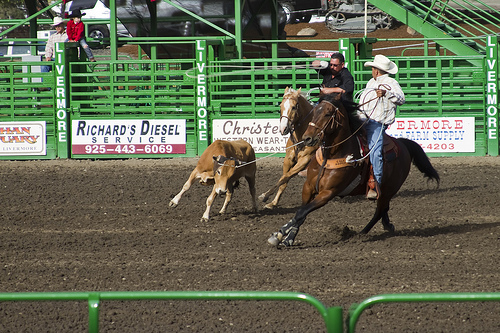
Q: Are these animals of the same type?
A: No, they are horses and bulls.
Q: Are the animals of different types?
A: Yes, they are horses and bulls.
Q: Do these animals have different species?
A: Yes, they are horses and bulls.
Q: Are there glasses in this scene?
A: No, there are no glasses.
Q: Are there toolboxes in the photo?
A: No, there are no toolboxes.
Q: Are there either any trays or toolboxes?
A: No, there are no toolboxes or trays.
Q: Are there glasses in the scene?
A: No, there are no glasses.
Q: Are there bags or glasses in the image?
A: No, there are no glasses or bags.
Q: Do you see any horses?
A: Yes, there is a horse.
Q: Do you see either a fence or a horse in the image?
A: Yes, there is a horse.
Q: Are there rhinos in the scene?
A: No, there are no rhinos.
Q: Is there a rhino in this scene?
A: No, there are no rhinos.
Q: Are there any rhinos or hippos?
A: No, there are no rhinos or hippos.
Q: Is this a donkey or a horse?
A: This is a horse.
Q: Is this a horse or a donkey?
A: This is a horse.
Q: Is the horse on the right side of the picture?
A: Yes, the horse is on the right of the image.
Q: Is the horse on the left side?
A: No, the horse is on the right of the image.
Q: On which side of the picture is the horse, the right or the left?
A: The horse is on the right of the image.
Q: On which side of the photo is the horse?
A: The horse is on the right of the image.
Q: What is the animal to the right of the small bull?
A: The animal is a horse.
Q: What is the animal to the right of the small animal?
A: The animal is a horse.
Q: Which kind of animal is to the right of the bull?
A: The animal is a horse.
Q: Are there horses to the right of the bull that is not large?
A: Yes, there is a horse to the right of the bull.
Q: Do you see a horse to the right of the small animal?
A: Yes, there is a horse to the right of the bull.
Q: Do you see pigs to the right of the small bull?
A: No, there is a horse to the right of the bull.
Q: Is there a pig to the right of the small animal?
A: No, there is a horse to the right of the bull.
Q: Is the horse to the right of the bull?
A: Yes, the horse is to the right of the bull.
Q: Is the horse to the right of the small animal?
A: Yes, the horse is to the right of the bull.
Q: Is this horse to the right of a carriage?
A: No, the horse is to the right of the bull.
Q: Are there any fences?
A: Yes, there is a fence.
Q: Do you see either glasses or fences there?
A: Yes, there is a fence.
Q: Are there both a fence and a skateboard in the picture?
A: No, there is a fence but no skateboards.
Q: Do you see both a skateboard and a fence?
A: No, there is a fence but no skateboards.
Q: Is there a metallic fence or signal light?
A: Yes, there is a metal fence.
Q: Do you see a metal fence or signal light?
A: Yes, there is a metal fence.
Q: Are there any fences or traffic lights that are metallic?
A: Yes, the fence is metallic.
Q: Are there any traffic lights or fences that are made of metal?
A: Yes, the fence is made of metal.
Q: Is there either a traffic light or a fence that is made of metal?
A: Yes, the fence is made of metal.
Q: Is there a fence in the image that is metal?
A: Yes, there is a metal fence.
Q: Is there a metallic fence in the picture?
A: Yes, there is a metal fence.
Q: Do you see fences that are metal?
A: Yes, there is a metal fence.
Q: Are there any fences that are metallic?
A: Yes, there is a fence that is metallic.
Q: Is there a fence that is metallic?
A: Yes, there is a fence that is metallic.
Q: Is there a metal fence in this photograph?
A: Yes, there is a fence that is made of metal.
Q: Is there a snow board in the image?
A: No, there are no snowboards.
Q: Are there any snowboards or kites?
A: No, there are no snowboards or kites.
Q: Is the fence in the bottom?
A: Yes, the fence is in the bottom of the image.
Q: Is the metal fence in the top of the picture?
A: No, the fence is in the bottom of the image.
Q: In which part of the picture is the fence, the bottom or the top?
A: The fence is in the bottom of the image.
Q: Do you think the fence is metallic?
A: Yes, the fence is metallic.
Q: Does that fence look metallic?
A: Yes, the fence is metallic.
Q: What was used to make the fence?
A: The fence is made of metal.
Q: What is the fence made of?
A: The fence is made of metal.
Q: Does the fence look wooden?
A: No, the fence is metallic.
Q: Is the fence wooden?
A: No, the fence is metallic.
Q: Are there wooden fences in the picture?
A: No, there is a fence but it is metallic.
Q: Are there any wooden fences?
A: No, there is a fence but it is metallic.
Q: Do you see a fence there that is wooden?
A: No, there is a fence but it is metallic.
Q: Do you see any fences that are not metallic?
A: No, there is a fence but it is metallic.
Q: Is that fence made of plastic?
A: No, the fence is made of metal.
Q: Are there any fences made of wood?
A: No, there is a fence but it is made of metal.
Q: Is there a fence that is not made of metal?
A: No, there is a fence but it is made of metal.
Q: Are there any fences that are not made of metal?
A: No, there is a fence but it is made of metal.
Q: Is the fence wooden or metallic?
A: The fence is metallic.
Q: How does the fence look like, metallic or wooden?
A: The fence is metallic.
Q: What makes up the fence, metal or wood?
A: The fence is made of metal.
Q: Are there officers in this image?
A: No, there are no officers.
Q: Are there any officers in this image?
A: No, there are no officers.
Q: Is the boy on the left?
A: Yes, the boy is on the left of the image.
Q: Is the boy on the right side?
A: No, the boy is on the left of the image.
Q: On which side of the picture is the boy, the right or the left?
A: The boy is on the left of the image.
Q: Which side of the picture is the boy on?
A: The boy is on the left of the image.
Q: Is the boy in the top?
A: Yes, the boy is in the top of the image.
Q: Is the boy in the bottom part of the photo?
A: No, the boy is in the top of the image.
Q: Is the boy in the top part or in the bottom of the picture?
A: The boy is in the top of the image.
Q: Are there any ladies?
A: No, there are no ladies.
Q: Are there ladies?
A: No, there are no ladies.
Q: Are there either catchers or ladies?
A: No, there are no ladies or catchers.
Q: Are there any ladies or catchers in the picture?
A: No, there are no ladies or catchers.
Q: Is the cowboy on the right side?
A: Yes, the cowboy is on the right of the image.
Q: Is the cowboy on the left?
A: No, the cowboy is on the right of the image.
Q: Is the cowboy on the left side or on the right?
A: The cowboy is on the right of the image.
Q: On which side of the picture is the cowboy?
A: The cowboy is on the right of the image.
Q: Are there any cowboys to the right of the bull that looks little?
A: Yes, there is a cowboy to the right of the bull.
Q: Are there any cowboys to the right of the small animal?
A: Yes, there is a cowboy to the right of the bull.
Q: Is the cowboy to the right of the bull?
A: Yes, the cowboy is to the right of the bull.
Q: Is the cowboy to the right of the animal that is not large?
A: Yes, the cowboy is to the right of the bull.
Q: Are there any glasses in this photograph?
A: No, there are no glasses.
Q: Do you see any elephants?
A: No, there are no elephants.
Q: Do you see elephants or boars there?
A: No, there are no elephants or boars.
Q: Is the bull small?
A: Yes, the bull is small.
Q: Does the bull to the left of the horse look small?
A: Yes, the bull is small.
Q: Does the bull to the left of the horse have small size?
A: Yes, the bull is small.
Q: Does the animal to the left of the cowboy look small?
A: Yes, the bull is small.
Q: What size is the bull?
A: The bull is small.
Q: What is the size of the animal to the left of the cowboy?
A: The bull is small.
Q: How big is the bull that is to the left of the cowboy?
A: The bull is small.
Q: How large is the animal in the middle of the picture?
A: The bull is small.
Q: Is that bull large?
A: No, the bull is small.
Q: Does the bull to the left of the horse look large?
A: No, the bull is small.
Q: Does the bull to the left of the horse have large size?
A: No, the bull is small.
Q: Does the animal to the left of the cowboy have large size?
A: No, the bull is small.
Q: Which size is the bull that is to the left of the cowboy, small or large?
A: The bull is small.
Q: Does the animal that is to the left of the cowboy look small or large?
A: The bull is small.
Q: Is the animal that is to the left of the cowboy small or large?
A: The bull is small.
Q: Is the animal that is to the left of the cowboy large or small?
A: The bull is small.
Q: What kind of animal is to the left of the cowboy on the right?
A: The animal is a bull.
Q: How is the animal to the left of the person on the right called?
A: The animal is a bull.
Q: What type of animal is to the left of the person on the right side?
A: The animal is a bull.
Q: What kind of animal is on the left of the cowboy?
A: The animal is a bull.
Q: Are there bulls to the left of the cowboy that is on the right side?
A: Yes, there is a bull to the left of the cowboy.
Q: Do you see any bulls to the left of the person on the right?
A: Yes, there is a bull to the left of the cowboy.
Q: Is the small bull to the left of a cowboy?
A: Yes, the bull is to the left of a cowboy.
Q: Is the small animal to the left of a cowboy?
A: Yes, the bull is to the left of a cowboy.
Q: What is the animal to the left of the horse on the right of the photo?
A: The animal is a bull.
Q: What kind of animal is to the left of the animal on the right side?
A: The animal is a bull.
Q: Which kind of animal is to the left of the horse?
A: The animal is a bull.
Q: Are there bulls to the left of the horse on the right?
A: Yes, there is a bull to the left of the horse.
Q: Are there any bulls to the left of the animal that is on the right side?
A: Yes, there is a bull to the left of the horse.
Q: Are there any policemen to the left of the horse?
A: No, there is a bull to the left of the horse.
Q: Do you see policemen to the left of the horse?
A: No, there is a bull to the left of the horse.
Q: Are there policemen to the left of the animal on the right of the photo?
A: No, there is a bull to the left of the horse.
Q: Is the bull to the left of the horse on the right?
A: Yes, the bull is to the left of the horse.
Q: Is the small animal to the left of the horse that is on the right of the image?
A: Yes, the bull is to the left of the horse.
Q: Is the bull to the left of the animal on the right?
A: Yes, the bull is to the left of the horse.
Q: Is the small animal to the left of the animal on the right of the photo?
A: Yes, the bull is to the left of the horse.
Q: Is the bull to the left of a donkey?
A: No, the bull is to the left of the horse.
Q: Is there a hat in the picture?
A: Yes, there is a hat.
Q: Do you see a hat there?
A: Yes, there is a hat.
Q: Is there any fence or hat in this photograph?
A: Yes, there is a hat.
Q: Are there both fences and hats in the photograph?
A: Yes, there are both a hat and a fence.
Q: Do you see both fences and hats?
A: Yes, there are both a hat and a fence.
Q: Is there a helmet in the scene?
A: No, there are no helmets.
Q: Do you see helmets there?
A: No, there are no helmets.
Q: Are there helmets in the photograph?
A: No, there are no helmets.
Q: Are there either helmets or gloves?
A: No, there are no helmets or gloves.